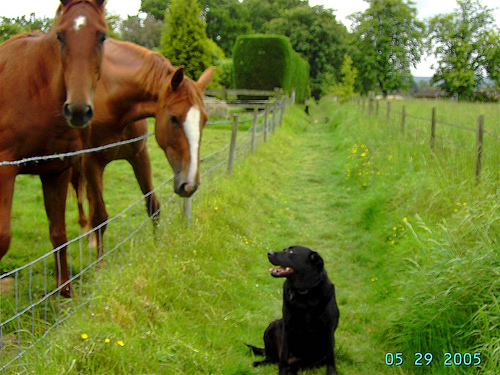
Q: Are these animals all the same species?
A: No, there are both horses and dogs.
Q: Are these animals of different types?
A: Yes, they are horses and dogs.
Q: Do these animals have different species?
A: Yes, they are horses and dogs.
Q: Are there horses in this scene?
A: Yes, there is a horse.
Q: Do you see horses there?
A: Yes, there is a horse.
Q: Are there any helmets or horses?
A: Yes, there is a horse.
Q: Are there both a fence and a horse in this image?
A: Yes, there are both a horse and a fence.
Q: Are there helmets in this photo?
A: No, there are no helmets.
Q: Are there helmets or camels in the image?
A: No, there are no helmets or camels.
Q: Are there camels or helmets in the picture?
A: No, there are no helmets or camels.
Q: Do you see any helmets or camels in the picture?
A: No, there are no helmets or camels.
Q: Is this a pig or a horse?
A: This is a horse.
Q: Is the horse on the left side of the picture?
A: Yes, the horse is on the left of the image.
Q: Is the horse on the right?
A: No, the horse is on the left of the image.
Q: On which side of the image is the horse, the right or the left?
A: The horse is on the left of the image.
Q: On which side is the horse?
A: The horse is on the left of the image.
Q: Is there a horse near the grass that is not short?
A: Yes, there is a horse near the grass.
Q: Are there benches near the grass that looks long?
A: No, there is a horse near the grass.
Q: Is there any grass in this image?
A: Yes, there is grass.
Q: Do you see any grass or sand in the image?
A: Yes, there is grass.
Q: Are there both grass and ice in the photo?
A: No, there is grass but no ice.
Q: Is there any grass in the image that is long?
A: Yes, there is long grass.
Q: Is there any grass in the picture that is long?
A: Yes, there is grass that is long.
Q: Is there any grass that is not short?
A: Yes, there is long grass.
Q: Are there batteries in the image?
A: No, there are no batteries.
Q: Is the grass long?
A: Yes, the grass is long.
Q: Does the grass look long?
A: Yes, the grass is long.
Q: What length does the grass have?
A: The grass has long length.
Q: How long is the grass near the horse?
A: The grass is long.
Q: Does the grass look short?
A: No, the grass is long.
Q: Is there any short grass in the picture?
A: No, there is grass but it is long.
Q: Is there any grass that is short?
A: No, there is grass but it is long.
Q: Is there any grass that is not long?
A: No, there is grass but it is long.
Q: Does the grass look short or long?
A: The grass is long.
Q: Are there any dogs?
A: Yes, there is a dog.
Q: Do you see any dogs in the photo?
A: Yes, there is a dog.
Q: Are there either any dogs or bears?
A: Yes, there is a dog.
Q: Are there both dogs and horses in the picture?
A: Yes, there are both a dog and a horse.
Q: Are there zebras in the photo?
A: No, there are no zebras.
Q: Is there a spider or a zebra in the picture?
A: No, there are no zebras or spiders.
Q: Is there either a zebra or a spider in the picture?
A: No, there are no zebras or spiders.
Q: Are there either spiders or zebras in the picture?
A: No, there are no zebras or spiders.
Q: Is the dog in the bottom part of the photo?
A: Yes, the dog is in the bottom of the image.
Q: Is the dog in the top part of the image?
A: No, the dog is in the bottom of the image.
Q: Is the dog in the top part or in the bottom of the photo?
A: The dog is in the bottom of the image.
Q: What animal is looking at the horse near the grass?
A: The dog is looking at the horse.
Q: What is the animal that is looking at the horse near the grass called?
A: The animal is a dog.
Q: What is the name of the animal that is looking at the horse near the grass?
A: The animal is a dog.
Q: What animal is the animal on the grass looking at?
A: The dog is looking at the horse.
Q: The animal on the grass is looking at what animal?
A: The dog is looking at the horse.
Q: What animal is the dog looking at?
A: The dog is looking at the horse.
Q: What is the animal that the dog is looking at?
A: The animal is a horse.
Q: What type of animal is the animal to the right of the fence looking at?
A: The dog is looking at the horse.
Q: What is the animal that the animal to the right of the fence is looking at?
A: The animal is a horse.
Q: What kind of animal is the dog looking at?
A: The dog is looking at the horse.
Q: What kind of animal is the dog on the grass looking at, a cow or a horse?
A: The dog is looking at a horse.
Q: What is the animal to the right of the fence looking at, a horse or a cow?
A: The dog is looking at a horse.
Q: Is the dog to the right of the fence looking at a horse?
A: Yes, the dog is looking at a horse.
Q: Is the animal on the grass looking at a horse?
A: Yes, the dog is looking at a horse.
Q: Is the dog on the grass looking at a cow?
A: No, the dog is looking at a horse.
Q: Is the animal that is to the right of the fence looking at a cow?
A: No, the dog is looking at a horse.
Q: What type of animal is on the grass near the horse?
A: The animal is a dog.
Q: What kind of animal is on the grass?
A: The animal is a dog.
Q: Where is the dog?
A: The dog is on the grass.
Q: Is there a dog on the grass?
A: Yes, there is a dog on the grass.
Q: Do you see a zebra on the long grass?
A: No, there is a dog on the grass.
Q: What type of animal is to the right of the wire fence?
A: The animal is a dog.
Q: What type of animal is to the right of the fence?
A: The animal is a dog.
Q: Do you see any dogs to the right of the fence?
A: Yes, there is a dog to the right of the fence.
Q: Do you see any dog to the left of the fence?
A: No, the dog is to the right of the fence.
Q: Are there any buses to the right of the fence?
A: No, there is a dog to the right of the fence.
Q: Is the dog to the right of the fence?
A: Yes, the dog is to the right of the fence.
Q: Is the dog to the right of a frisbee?
A: No, the dog is to the right of the fence.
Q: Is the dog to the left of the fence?
A: No, the dog is to the right of the fence.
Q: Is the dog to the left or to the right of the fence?
A: The dog is to the right of the fence.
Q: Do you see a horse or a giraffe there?
A: Yes, there is a horse.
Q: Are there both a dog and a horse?
A: Yes, there are both a horse and a dog.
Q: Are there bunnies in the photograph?
A: No, there are no bunnies.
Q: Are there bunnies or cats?
A: No, there are no bunnies or cats.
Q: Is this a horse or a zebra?
A: This is a horse.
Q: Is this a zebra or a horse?
A: This is a horse.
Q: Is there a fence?
A: Yes, there is a fence.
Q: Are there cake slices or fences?
A: Yes, there is a fence.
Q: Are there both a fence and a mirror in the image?
A: No, there is a fence but no mirrors.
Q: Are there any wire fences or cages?
A: Yes, there is a wire fence.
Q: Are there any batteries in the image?
A: No, there are no batteries.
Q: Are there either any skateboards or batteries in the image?
A: No, there are no batteries or skateboards.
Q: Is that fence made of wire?
A: Yes, the fence is made of wire.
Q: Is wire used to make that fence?
A: Yes, the fence is made of wire.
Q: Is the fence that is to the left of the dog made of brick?
A: No, the fence is made of wire.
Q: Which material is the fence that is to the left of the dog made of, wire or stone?
A: The fence is made of wire.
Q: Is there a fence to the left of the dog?
A: Yes, there is a fence to the left of the dog.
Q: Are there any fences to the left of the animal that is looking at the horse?
A: Yes, there is a fence to the left of the dog.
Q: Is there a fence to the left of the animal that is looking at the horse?
A: Yes, there is a fence to the left of the dog.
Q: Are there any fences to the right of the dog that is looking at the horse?
A: No, the fence is to the left of the dog.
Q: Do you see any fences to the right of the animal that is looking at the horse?
A: No, the fence is to the left of the dog.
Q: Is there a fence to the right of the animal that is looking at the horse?
A: No, the fence is to the left of the dog.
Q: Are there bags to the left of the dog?
A: No, there is a fence to the left of the dog.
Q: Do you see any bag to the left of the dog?
A: No, there is a fence to the left of the dog.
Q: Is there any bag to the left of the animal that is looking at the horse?
A: No, there is a fence to the left of the dog.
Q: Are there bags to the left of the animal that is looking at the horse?
A: No, there is a fence to the left of the dog.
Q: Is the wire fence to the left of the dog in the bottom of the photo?
A: Yes, the fence is to the left of the dog.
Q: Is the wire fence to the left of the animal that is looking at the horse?
A: Yes, the fence is to the left of the dog.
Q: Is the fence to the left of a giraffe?
A: No, the fence is to the left of the dog.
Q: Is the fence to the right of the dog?
A: No, the fence is to the left of the dog.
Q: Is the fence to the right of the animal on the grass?
A: No, the fence is to the left of the dog.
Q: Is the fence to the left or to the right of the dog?
A: The fence is to the left of the dog.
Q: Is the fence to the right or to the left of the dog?
A: The fence is to the left of the dog.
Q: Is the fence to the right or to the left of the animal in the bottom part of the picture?
A: The fence is to the left of the dog.